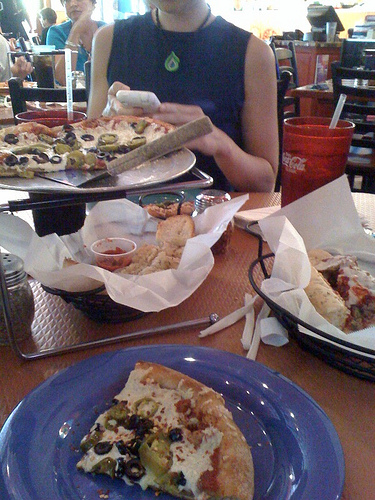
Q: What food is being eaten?
A: Pizza.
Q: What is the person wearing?
A: Black shirt.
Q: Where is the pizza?
A: On that plate.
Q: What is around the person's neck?
A: Necklace.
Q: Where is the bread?
A: In the baskets.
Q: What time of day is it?
A: Afternoon.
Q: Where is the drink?
A: In the cup,.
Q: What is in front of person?
A: Pizza.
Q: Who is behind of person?
A: A woman.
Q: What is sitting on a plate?
A: A slice of pizza.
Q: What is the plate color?
A: Blue.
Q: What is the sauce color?
A: Red.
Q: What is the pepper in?
A: A clear container.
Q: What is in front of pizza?
A: Cup.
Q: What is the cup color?
A: Red.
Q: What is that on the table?
A: Pizza on plate.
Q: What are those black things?
A: Olives on pizza.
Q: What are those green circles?
A: Jalapenos on pizza.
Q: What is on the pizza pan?
A: Metal pie server.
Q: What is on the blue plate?
A: Pizza with olives and jalapenos.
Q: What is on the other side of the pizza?
A: Person in black top.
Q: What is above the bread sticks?
A: Half pizza on tray.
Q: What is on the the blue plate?
A: Big pizza.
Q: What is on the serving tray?
A: Half a pizza.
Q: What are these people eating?
A: Pizza.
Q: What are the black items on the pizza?
A: Olives.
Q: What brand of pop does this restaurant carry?
A: Coca-cola.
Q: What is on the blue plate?
A: Pizza.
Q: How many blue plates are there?
A: One.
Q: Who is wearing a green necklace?
A: The woman.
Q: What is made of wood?
A: The table.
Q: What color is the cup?
A: Red.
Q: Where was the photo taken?
A: In a restaurant.